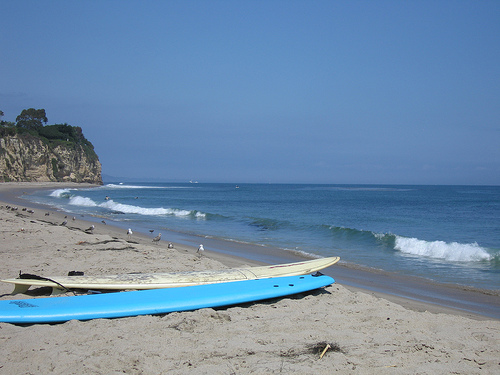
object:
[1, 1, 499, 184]
sky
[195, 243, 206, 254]
seagull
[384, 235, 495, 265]
waves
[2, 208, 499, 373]
beach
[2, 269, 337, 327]
surfboard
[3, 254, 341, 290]
surfboard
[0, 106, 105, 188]
cliff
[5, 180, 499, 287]
ocean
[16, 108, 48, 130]
vegetation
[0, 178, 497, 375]
sand